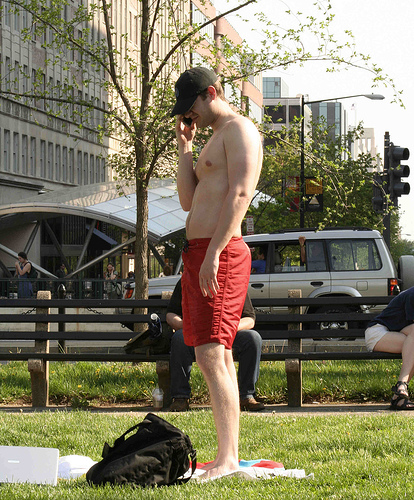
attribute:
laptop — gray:
[0, 442, 65, 482]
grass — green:
[227, 479, 359, 497]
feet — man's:
[172, 395, 313, 482]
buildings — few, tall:
[256, 68, 383, 188]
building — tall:
[265, 80, 314, 164]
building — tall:
[307, 86, 354, 160]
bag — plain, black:
[90, 398, 205, 494]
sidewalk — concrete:
[0, 392, 413, 414]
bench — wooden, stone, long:
[4, 289, 412, 404]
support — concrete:
[285, 288, 302, 405]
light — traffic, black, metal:
[385, 144, 409, 200]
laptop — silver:
[0, 443, 62, 489]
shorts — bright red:
[179, 232, 251, 350]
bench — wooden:
[0, 287, 160, 410]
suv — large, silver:
[115, 227, 399, 339]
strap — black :
[172, 441, 213, 493]